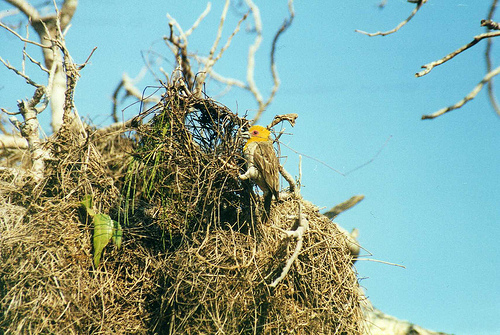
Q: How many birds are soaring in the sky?
A: 0.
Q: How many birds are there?
A: 1.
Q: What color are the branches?
A: Brown.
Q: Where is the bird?
A: In the nest.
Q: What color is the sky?
A: Blue.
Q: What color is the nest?
A: Brown.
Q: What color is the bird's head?
A: Yellow.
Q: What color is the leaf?
A: Green.